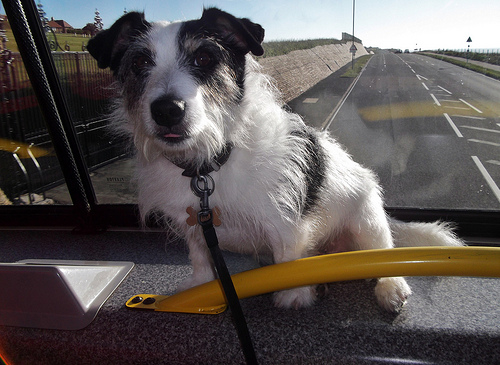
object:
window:
[0, 0, 499, 211]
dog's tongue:
[163, 130, 183, 137]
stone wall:
[256, 41, 371, 107]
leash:
[199, 218, 260, 365]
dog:
[85, 5, 473, 314]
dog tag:
[184, 205, 222, 227]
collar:
[165, 143, 234, 178]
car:
[0, 0, 500, 365]